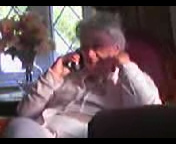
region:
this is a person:
[12, 10, 159, 139]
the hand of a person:
[14, 40, 73, 121]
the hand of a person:
[114, 50, 170, 105]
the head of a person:
[64, 7, 128, 77]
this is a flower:
[21, 36, 55, 52]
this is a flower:
[1, 19, 16, 33]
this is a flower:
[11, 30, 33, 52]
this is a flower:
[20, 15, 38, 35]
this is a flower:
[4, 31, 25, 55]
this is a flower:
[27, 42, 57, 55]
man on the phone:
[10, 15, 166, 142]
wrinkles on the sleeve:
[25, 67, 65, 102]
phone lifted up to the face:
[64, 48, 85, 71]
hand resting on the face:
[110, 51, 130, 67]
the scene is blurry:
[0, 6, 175, 139]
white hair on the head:
[71, 12, 130, 46]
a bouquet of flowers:
[0, 14, 60, 79]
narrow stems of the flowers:
[23, 65, 36, 80]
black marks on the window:
[52, 5, 83, 55]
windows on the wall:
[0, 5, 106, 85]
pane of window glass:
[0, 3, 11, 18]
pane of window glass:
[6, 3, 20, 23]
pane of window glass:
[12, 2, 32, 15]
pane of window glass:
[1, 45, 28, 75]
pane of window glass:
[47, 3, 66, 24]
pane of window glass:
[67, 2, 85, 20]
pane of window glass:
[52, 2, 83, 47]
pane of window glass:
[51, 26, 70, 64]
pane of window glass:
[68, 30, 84, 54]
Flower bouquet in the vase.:
[1, 17, 55, 66]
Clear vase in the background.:
[12, 53, 46, 100]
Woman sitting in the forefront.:
[6, 12, 162, 137]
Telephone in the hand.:
[70, 45, 84, 70]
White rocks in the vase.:
[15, 77, 38, 93]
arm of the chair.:
[84, 102, 173, 137]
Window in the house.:
[1, 5, 86, 82]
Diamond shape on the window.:
[52, 6, 81, 48]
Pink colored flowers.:
[0, 12, 52, 54]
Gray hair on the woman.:
[73, 10, 126, 76]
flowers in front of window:
[0, 4, 79, 79]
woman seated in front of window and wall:
[3, 10, 154, 131]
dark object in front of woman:
[81, 101, 169, 130]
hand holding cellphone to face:
[46, 37, 76, 67]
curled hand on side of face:
[103, 44, 123, 61]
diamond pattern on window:
[49, 2, 74, 38]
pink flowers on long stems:
[0, 10, 47, 71]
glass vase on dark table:
[0, 56, 34, 107]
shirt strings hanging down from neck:
[23, 65, 149, 127]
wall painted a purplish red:
[101, 0, 173, 113]